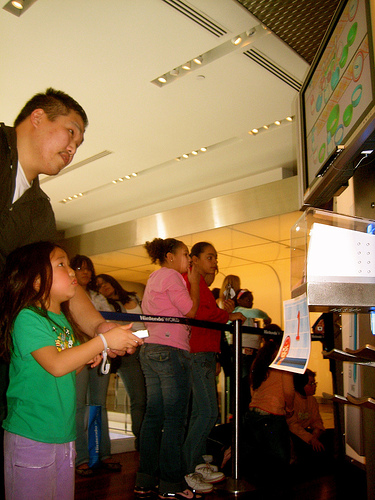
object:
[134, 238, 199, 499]
girl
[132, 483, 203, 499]
shoes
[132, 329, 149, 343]
controller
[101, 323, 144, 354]
hand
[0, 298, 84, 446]
shirt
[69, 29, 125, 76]
ceiling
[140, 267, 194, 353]
shirt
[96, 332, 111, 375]
wii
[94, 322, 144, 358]
hand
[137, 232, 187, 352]
banana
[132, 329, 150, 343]
wii remote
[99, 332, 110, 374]
wristband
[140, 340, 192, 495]
jeans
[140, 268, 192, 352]
pink shirt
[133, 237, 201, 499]
woman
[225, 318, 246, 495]
pole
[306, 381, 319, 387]
glasses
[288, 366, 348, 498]
lady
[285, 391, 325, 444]
sweater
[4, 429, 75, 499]
purple pants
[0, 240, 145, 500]
girl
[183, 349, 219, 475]
jeans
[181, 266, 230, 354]
jacket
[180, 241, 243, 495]
girl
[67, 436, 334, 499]
floor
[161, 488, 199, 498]
sneaker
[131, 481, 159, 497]
sneaker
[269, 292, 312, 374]
paper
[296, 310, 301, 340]
1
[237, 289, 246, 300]
headband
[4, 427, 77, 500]
pants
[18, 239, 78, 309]
girl's head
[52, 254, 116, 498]
woman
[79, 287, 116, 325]
shirt